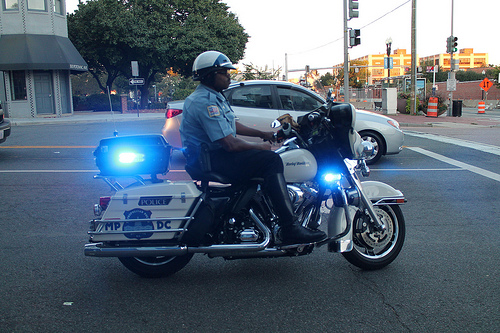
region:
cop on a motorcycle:
[53, 30, 427, 275]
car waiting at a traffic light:
[155, 59, 402, 161]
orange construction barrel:
[421, 93, 443, 118]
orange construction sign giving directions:
[467, 70, 496, 97]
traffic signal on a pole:
[337, 5, 364, 60]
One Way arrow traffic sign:
[125, 74, 147, 88]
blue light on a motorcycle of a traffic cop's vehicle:
[97, 136, 155, 169]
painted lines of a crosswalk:
[407, 133, 497, 178]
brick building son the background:
[360, 52, 482, 78]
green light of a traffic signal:
[446, 43, 462, 53]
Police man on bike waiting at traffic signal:
[41, 50, 409, 270]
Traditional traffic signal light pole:
[341, 1, 371, 107]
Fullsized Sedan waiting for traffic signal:
[166, 76, 406, 156]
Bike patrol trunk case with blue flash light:
[95, 134, 172, 175]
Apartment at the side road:
[2, 0, 84, 121]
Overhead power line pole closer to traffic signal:
[409, 2, 416, 118]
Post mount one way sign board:
[127, 75, 146, 118]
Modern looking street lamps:
[383, 32, 396, 114]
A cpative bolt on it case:
[190, 143, 212, 173]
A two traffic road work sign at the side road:
[481, 76, 492, 111]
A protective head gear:
[202, 57, 217, 62]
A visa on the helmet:
[229, 67, 234, 68]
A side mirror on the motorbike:
[273, 124, 278, 126]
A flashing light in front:
[328, 175, 334, 180]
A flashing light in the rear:
[117, 154, 134, 160]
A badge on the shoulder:
[210, 106, 215, 113]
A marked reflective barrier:
[479, 104, 483, 111]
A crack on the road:
[395, 311, 397, 317]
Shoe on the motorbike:
[288, 237, 313, 244]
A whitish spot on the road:
[63, 301, 70, 305]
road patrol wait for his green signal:
[82, 50, 495, 275]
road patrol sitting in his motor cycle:
[85, 50, 405, 270]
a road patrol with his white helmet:
[187, 47, 318, 262]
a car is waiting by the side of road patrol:
[82, 51, 407, 276]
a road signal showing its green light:
[446, 0, 465, 117]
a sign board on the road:
[124, 56, 151, 118]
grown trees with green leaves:
[73, 0, 247, 114]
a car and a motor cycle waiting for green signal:
[84, 48, 499, 278]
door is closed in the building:
[19, 30, 81, 134]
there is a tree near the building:
[8, 3, 127, 120]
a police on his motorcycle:
[84, 49, 406, 283]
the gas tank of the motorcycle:
[282, 148, 317, 183]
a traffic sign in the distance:
[475, 78, 495, 97]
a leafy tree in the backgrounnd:
[76, 1, 253, 58]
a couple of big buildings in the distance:
[337, 52, 490, 76]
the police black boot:
[265, 173, 326, 248]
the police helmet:
[191, 53, 237, 72]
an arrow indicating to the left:
[126, 76, 146, 88]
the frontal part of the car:
[380, 117, 407, 153]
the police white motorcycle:
[63, 115, 408, 269]